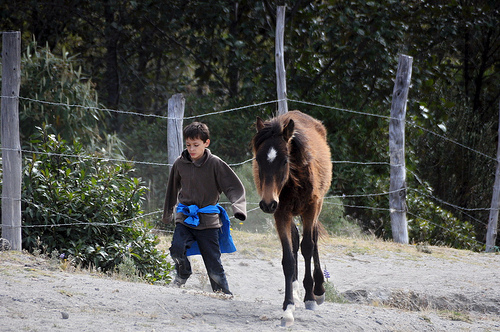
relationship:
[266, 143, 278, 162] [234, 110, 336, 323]
spot on horse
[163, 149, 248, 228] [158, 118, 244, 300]
hoodie on boy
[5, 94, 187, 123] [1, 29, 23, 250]
wire on stick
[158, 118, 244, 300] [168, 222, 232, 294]
boy has jeans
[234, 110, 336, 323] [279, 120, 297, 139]
horse has ear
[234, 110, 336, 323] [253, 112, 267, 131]
horse has ear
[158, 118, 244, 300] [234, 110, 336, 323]
boy has animal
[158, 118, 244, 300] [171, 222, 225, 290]
boy has jeans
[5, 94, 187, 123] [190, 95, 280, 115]
wire on fence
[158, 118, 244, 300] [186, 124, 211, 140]
boy has hair